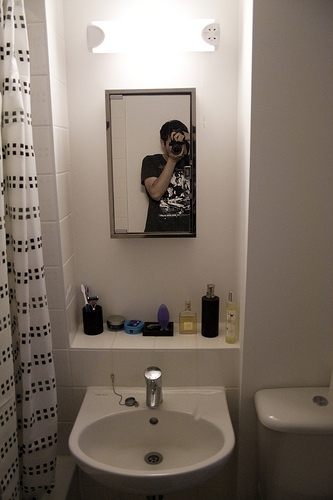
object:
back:
[252, 382, 333, 498]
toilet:
[251, 384, 333, 499]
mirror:
[110, 91, 193, 235]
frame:
[104, 87, 197, 240]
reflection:
[139, 117, 195, 236]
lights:
[167, 34, 172, 42]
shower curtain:
[0, 0, 62, 500]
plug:
[109, 373, 140, 408]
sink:
[66, 364, 238, 496]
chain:
[109, 372, 125, 406]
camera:
[169, 137, 190, 160]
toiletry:
[225, 289, 238, 344]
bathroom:
[0, 0, 332, 500]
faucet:
[143, 365, 165, 410]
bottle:
[178, 298, 198, 335]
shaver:
[87, 295, 100, 311]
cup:
[81, 302, 105, 336]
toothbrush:
[80, 283, 91, 312]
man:
[140, 118, 193, 234]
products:
[157, 302, 170, 332]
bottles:
[201, 283, 220, 338]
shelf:
[70, 321, 241, 352]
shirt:
[140, 152, 192, 233]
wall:
[23, 0, 333, 458]